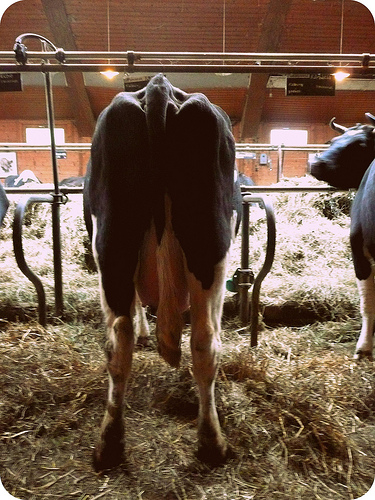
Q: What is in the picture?
A: Cows.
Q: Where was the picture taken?
A: Stable.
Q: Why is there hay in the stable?
A: Food for cows.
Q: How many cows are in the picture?
A: Two.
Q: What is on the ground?
A: Hay.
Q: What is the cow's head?
A: Horns.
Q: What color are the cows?
A: Black.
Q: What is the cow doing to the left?
A: Eating.